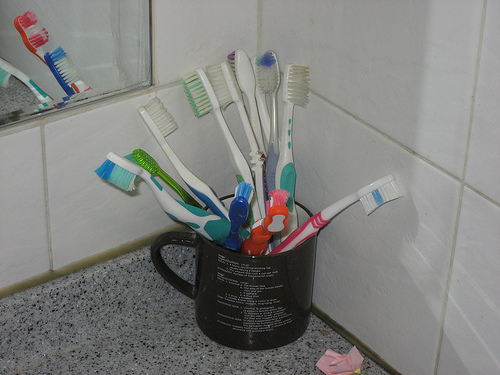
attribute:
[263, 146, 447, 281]
toothbrush — orange, white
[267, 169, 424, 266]
toothbrush — pink, white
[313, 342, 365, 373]
pink paper — rumpled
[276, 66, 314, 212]
toothbrush — green, white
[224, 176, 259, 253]
tooth brush — blue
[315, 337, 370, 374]
pink paper — crumbled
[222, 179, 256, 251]
toothbrush — blue, white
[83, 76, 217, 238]
tooth brush — orange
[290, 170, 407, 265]
toothbrush — pink, white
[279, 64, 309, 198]
toothbrush — white, pink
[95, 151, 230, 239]
toothbrush — pink, white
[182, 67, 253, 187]
toothbrush — white, pink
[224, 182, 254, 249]
blue toothbrush —   Tooth , blue 'body' 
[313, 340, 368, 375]
paper — pink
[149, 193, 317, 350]
coffee mug — black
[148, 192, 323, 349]
mug — white, black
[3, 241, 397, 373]
countertop — gray, black, granite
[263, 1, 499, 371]
wall — white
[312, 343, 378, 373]
paper — pink piece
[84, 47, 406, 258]
toothbrushes — reflection 